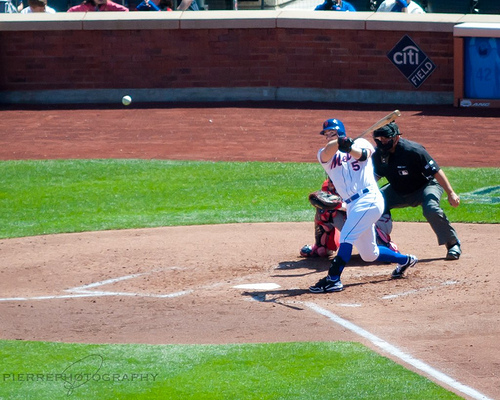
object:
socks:
[328, 242, 354, 281]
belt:
[344, 184, 372, 205]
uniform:
[314, 139, 412, 273]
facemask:
[372, 120, 402, 154]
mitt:
[307, 190, 342, 212]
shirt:
[374, 138, 442, 192]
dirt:
[96, 239, 250, 320]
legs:
[348, 206, 405, 267]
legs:
[328, 191, 385, 280]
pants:
[328, 191, 400, 277]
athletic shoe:
[308, 276, 344, 294]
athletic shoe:
[389, 253, 419, 280]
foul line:
[2, 282, 87, 306]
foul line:
[307, 295, 500, 400]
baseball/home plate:
[232, 281, 283, 291]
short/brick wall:
[1, 26, 450, 96]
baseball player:
[308, 118, 417, 294]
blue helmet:
[320, 118, 347, 139]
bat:
[351, 109, 401, 143]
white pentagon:
[229, 277, 283, 296]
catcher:
[373, 117, 462, 261]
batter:
[306, 109, 416, 294]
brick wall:
[1, 12, 484, 103]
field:
[0, 100, 483, 390]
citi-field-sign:
[385, 33, 435, 86]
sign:
[383, 28, 436, 93]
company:
[2, 350, 152, 394]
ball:
[121, 95, 132, 106]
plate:
[229, 282, 282, 295]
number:
[350, 161, 361, 172]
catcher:
[300, 172, 401, 257]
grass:
[3, 338, 462, 397]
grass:
[2, 155, 481, 254]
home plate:
[233, 283, 282, 291]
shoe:
[308, 273, 343, 293]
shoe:
[390, 254, 419, 279]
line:
[1, 268, 205, 313]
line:
[301, 295, 484, 397]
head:
[319, 118, 346, 143]